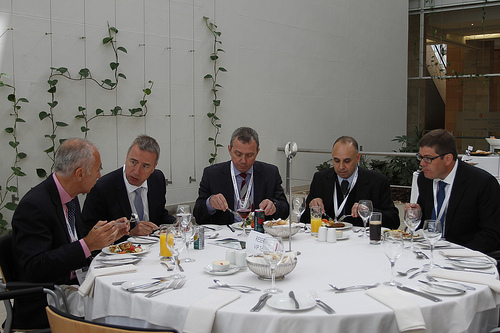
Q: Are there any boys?
A: No, there are no boys.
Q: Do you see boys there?
A: No, there are no boys.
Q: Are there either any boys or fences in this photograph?
A: No, there are no boys or fences.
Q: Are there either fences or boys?
A: No, there are no boys or fences.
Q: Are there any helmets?
A: No, there are no helmets.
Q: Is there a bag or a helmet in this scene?
A: No, there are no helmets or bags.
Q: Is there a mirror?
A: No, there are no mirrors.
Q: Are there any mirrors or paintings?
A: No, there are no mirrors or paintings.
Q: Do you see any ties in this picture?
A: Yes, there is a tie.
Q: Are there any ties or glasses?
A: Yes, there is a tie.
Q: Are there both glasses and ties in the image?
A: Yes, there are both a tie and glasses.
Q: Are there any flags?
A: No, there are no flags.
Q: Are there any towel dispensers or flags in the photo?
A: No, there are no flags or towel dispensers.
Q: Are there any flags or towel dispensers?
A: No, there are no flags or towel dispensers.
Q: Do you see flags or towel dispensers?
A: No, there are no flags or towel dispensers.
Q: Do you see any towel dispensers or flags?
A: No, there are no flags or towel dispensers.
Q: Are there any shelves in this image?
A: No, there are no shelves.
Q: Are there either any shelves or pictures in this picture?
A: No, there are no shelves or pictures.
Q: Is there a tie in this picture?
A: Yes, there is a tie.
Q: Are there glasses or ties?
A: Yes, there is a tie.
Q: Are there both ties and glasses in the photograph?
A: Yes, there are both a tie and glasses.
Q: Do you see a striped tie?
A: Yes, there is a striped tie.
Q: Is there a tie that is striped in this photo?
A: Yes, there is a striped tie.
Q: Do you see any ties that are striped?
A: Yes, there is a tie that is striped.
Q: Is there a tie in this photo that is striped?
A: Yes, there is a tie that is striped.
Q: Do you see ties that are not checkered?
A: Yes, there is a striped tie.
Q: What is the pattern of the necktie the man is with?
A: The necktie is striped.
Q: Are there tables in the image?
A: Yes, there is a table.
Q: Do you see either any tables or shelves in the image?
A: Yes, there is a table.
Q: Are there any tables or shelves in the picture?
A: Yes, there is a table.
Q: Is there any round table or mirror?
A: Yes, there is a round table.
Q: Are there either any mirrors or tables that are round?
A: Yes, the table is round.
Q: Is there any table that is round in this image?
A: Yes, there is a round table.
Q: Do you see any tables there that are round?
A: Yes, there is a table that is round.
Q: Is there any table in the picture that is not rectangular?
A: Yes, there is a round table.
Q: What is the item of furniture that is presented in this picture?
A: The piece of furniture is a table.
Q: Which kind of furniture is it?
A: The piece of furniture is a table.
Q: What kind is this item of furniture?
A: This is a table.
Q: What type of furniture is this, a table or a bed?
A: This is a table.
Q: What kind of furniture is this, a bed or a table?
A: This is a table.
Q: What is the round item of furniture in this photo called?
A: The piece of furniture is a table.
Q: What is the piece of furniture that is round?
A: The piece of furniture is a table.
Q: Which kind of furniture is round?
A: The furniture is a table.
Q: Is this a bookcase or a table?
A: This is a table.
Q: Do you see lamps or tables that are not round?
A: No, there is a table but it is round.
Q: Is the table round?
A: Yes, the table is round.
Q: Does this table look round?
A: Yes, the table is round.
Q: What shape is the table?
A: The table is round.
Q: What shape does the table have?
A: The table has round shape.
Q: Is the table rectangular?
A: No, the table is round.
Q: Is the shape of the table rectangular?
A: No, the table is round.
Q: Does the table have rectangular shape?
A: No, the table is round.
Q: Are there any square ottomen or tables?
A: No, there is a table but it is round.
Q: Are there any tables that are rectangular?
A: No, there is a table but it is round.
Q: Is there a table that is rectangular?
A: No, there is a table but it is round.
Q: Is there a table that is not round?
A: No, there is a table but it is round.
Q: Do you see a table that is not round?
A: No, there is a table but it is round.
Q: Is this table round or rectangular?
A: The table is round.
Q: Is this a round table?
A: Yes, this is a round table.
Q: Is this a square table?
A: No, this is a round table.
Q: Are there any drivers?
A: No, there are no drivers.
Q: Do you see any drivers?
A: No, there are no drivers.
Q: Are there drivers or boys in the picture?
A: No, there are no drivers or boys.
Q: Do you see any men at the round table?
A: Yes, there is a man at the table.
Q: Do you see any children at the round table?
A: No, there is a man at the table.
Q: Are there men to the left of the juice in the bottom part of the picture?
A: Yes, there is a man to the left of the juice.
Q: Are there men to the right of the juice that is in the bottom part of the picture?
A: No, the man is to the left of the juice.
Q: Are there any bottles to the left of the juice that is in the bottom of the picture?
A: No, there is a man to the left of the juice.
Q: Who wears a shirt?
A: The man wears a shirt.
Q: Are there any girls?
A: No, there are no girls.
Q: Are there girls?
A: No, there are no girls.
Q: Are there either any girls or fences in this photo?
A: No, there are no girls or fences.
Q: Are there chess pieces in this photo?
A: No, there are no chess pieces.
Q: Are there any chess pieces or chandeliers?
A: No, there are no chess pieces or chandeliers.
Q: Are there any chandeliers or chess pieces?
A: No, there are no chess pieces or chandeliers.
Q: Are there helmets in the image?
A: No, there are no helmets.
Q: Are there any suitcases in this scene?
A: No, there are no suitcases.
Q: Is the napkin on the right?
A: Yes, the napkin is on the right of the image.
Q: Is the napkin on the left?
A: No, the napkin is on the right of the image.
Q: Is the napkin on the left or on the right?
A: The napkin is on the right of the image.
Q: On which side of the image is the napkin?
A: The napkin is on the right of the image.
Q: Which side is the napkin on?
A: The napkin is on the right of the image.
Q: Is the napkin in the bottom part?
A: Yes, the napkin is in the bottom of the image.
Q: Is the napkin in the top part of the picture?
A: No, the napkin is in the bottom of the image.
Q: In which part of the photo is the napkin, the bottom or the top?
A: The napkin is in the bottom of the image.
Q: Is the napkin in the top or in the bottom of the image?
A: The napkin is in the bottom of the image.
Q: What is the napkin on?
A: The napkin is on the table.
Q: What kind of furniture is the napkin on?
A: The napkin is on the table.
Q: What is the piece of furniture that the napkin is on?
A: The piece of furniture is a table.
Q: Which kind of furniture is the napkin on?
A: The napkin is on the table.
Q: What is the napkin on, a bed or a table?
A: The napkin is on a table.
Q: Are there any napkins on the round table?
A: Yes, there is a napkin on the table.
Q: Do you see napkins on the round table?
A: Yes, there is a napkin on the table.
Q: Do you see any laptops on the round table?
A: No, there is a napkin on the table.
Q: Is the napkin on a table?
A: Yes, the napkin is on a table.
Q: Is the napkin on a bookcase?
A: No, the napkin is on a table.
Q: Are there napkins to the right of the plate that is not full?
A: Yes, there is a napkin to the right of the plate.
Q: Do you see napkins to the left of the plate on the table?
A: No, the napkin is to the right of the plate.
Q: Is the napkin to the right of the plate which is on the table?
A: Yes, the napkin is to the right of the plate.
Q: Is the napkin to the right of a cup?
A: No, the napkin is to the right of the plate.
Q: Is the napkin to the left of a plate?
A: No, the napkin is to the right of a plate.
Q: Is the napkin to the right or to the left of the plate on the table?
A: The napkin is to the right of the plate.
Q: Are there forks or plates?
A: Yes, there is a plate.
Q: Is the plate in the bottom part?
A: Yes, the plate is in the bottom of the image.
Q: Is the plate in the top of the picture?
A: No, the plate is in the bottom of the image.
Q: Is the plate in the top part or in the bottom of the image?
A: The plate is in the bottom of the image.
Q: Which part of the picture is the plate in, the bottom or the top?
A: The plate is in the bottom of the image.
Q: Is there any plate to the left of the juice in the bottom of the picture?
A: Yes, there is a plate to the left of the juice.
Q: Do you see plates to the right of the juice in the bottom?
A: No, the plate is to the left of the juice.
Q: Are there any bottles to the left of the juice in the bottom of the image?
A: No, there is a plate to the left of the juice.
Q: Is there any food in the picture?
A: Yes, there is food.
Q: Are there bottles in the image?
A: No, there are no bottles.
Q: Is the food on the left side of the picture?
A: Yes, the food is on the left of the image.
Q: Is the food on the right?
A: No, the food is on the left of the image.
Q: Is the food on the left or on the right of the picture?
A: The food is on the left of the image.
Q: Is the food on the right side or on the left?
A: The food is on the left of the image.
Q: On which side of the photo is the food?
A: The food is on the left of the image.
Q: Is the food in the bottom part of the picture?
A: Yes, the food is in the bottom of the image.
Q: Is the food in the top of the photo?
A: No, the food is in the bottom of the image.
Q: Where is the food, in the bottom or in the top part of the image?
A: The food is in the bottom of the image.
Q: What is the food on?
A: The food is on the plate.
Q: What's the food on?
A: The food is on the plate.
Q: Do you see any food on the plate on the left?
A: Yes, there is food on the plate.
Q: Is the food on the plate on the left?
A: Yes, the food is on the plate.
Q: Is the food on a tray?
A: No, the food is on the plate.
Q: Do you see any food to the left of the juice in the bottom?
A: Yes, there is food to the left of the juice.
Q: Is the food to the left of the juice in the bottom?
A: Yes, the food is to the left of the juice.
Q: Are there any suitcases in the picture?
A: No, there are no suitcases.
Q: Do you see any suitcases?
A: No, there are no suitcases.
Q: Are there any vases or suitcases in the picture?
A: No, there are no suitcases or vases.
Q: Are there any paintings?
A: No, there are no paintings.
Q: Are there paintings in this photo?
A: No, there are no paintings.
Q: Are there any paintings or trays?
A: No, there are no paintings or trays.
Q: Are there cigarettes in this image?
A: No, there are no cigarettes.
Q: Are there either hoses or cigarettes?
A: No, there are no cigarettes or hoses.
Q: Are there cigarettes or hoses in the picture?
A: No, there are no cigarettes or hoses.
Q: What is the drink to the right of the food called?
A: The drink is juice.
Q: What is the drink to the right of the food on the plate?
A: The drink is juice.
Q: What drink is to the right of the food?
A: The drink is juice.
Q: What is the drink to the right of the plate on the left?
A: The drink is juice.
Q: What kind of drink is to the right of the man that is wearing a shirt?
A: The drink is juice.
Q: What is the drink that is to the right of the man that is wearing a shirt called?
A: The drink is juice.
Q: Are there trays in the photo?
A: No, there are no trays.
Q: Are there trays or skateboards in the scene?
A: No, there are no trays or skateboards.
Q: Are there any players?
A: No, there are no players.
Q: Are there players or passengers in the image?
A: No, there are no players or passengers.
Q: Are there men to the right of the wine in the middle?
A: Yes, there is a man to the right of the wine.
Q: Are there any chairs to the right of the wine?
A: No, there is a man to the right of the wine.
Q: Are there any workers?
A: No, there are no workers.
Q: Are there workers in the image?
A: No, there are no workers.